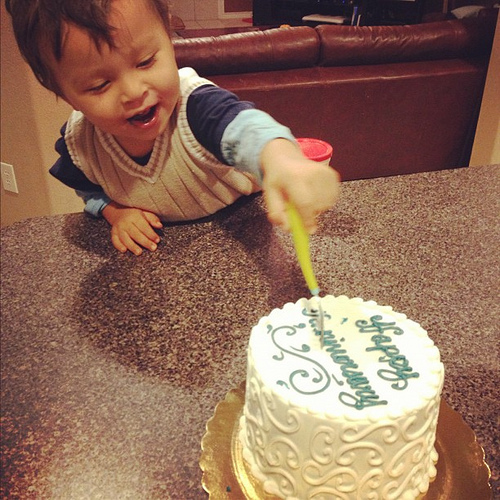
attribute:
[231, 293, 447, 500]
cake — white, frosted, decorated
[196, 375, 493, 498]
cardboard — gold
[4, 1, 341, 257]
boy — standing, smiling, amused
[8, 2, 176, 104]
hair — short, brown, thin, mussed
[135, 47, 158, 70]
eye — open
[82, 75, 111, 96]
eye — open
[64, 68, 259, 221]
vest — white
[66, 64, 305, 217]
shirt — blue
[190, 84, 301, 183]
sleeve — long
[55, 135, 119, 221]
sleeve — long